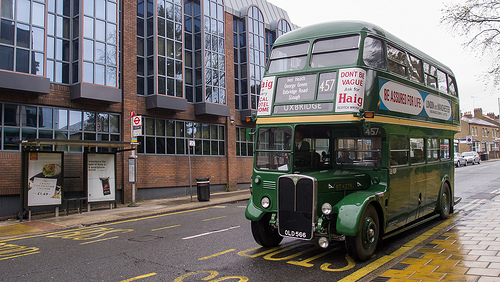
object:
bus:
[240, 18, 465, 263]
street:
[0, 160, 498, 282]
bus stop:
[18, 136, 142, 224]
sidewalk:
[0, 186, 253, 241]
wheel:
[344, 202, 386, 266]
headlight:
[319, 201, 334, 216]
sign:
[129, 114, 145, 138]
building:
[2, 0, 303, 216]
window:
[81, 60, 95, 84]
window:
[93, 61, 108, 87]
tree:
[437, 0, 500, 95]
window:
[311, 33, 360, 53]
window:
[308, 48, 361, 69]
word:
[235, 240, 380, 274]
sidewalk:
[368, 193, 499, 282]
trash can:
[194, 176, 212, 203]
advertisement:
[333, 66, 368, 116]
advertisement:
[372, 76, 454, 123]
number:
[318, 80, 325, 92]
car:
[460, 150, 482, 165]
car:
[453, 152, 469, 168]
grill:
[276, 173, 316, 239]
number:
[283, 228, 308, 239]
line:
[194, 246, 240, 264]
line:
[151, 223, 185, 233]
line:
[180, 223, 242, 241]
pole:
[186, 134, 194, 203]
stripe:
[256, 111, 462, 133]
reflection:
[77, 0, 123, 87]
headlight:
[259, 195, 272, 209]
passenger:
[336, 148, 353, 164]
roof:
[271, 15, 456, 74]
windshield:
[331, 131, 385, 170]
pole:
[129, 110, 140, 205]